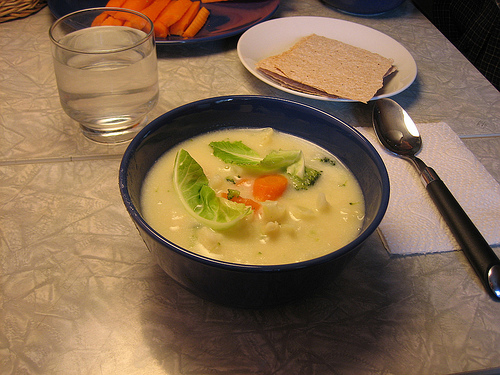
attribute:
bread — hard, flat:
[293, 57, 370, 89]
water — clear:
[66, 67, 146, 128]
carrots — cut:
[170, 6, 203, 31]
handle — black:
[430, 184, 484, 267]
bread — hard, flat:
[301, 44, 378, 91]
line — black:
[84, 270, 122, 279]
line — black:
[87, 228, 124, 244]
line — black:
[97, 264, 119, 281]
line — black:
[90, 252, 117, 264]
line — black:
[78, 245, 127, 265]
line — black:
[10, 265, 51, 277]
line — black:
[172, 349, 187, 372]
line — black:
[11, 150, 62, 170]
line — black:
[73, 251, 117, 264]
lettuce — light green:
[172, 156, 232, 220]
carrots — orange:
[214, 173, 293, 219]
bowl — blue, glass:
[114, 91, 394, 315]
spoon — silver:
[372, 97, 484, 261]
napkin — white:
[346, 120, 484, 256]